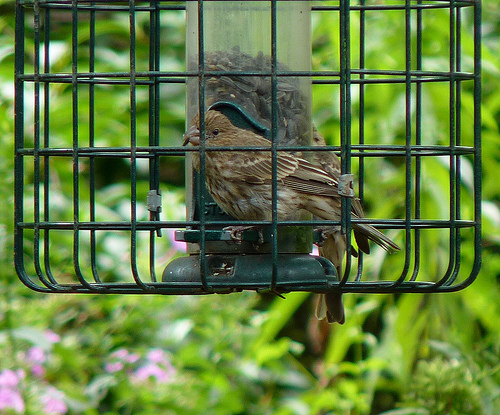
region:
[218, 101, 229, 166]
The eye of this bird is a very dark black color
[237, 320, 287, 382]
There is some very dark green vegetation here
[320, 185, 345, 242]
There are some tail feathers on this bird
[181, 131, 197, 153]
This bird has a large beak here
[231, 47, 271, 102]
There is a great deal of birdseed here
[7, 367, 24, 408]
There are purple flowers that are visible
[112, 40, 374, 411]
Jackson Mingus took this photo lately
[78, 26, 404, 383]
This photo has a wonder level of detail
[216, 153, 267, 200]
A bird in the cage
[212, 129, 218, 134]
The eye of the bird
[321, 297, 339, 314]
Tail feathers sticking out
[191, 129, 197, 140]
The beak of a bird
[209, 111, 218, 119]
Feathers on the head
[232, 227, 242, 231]
The claws of the bird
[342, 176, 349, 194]
Clip holding two wires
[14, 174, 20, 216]
A cage wire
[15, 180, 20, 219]
Wire painted green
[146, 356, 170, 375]
Reflection on leaves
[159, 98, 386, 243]
This is a bird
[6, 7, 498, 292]
The cage is made of green wire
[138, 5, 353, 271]
Gate to open the cage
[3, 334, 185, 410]
Pink flowers in the bottom left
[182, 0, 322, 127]
Container of bird seed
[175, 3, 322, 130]
The bird seed container is plastic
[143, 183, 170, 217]
A small metal hinge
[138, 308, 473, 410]
Green bushes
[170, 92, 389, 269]
bird inside a cage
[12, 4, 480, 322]
cage bird is in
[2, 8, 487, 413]
leaves and green plants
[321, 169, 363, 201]
metal bracket on cage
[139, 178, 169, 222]
metal bracket on cage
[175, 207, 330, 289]
ledge for bird to sit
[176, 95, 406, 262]
brown bird in a bird feeder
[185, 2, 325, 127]
brown food in a bird feeder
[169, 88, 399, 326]
brown bird in a bird feeder sitting on a perch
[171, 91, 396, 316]
bird in a bird feeder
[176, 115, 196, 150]
brown birds beak in the feeder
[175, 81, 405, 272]
brown bird in a bird feeder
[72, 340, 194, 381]
pink flowers in the background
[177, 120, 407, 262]
brown bird in a bird feeder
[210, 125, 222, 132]
brown bird in a bird feeder eye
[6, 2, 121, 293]
wire cage with a brown bird in it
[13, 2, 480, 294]
green metal cage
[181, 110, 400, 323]
bird in a green cage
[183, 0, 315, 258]
a bird feeder in a cage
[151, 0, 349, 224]
a door on a bird cage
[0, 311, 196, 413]
a flowering bush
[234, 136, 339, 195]
a wing on a bird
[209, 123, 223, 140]
Eye of a bird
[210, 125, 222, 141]
Black eye of a bird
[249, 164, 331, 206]
Feathers of a bird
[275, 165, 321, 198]
Feathers of a bird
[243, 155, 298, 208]
Feathers of a bird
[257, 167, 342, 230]
Feathers of a bird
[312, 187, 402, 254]
Feathers of a bird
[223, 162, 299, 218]
Feathers of a bird